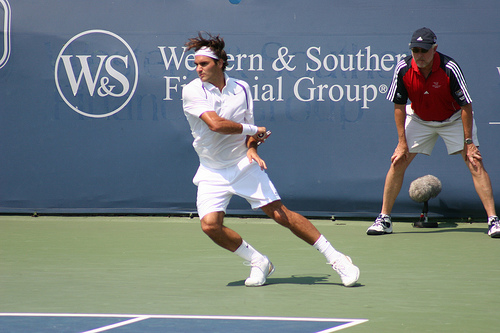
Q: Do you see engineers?
A: No, there are no engineers.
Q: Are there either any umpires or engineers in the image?
A: No, there are no engineers or umpires.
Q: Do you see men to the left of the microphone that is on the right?
A: Yes, there is a man to the left of the microphone.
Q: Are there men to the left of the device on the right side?
A: Yes, there is a man to the left of the microphone.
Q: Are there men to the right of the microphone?
A: No, the man is to the left of the microphone.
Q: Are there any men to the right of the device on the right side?
A: No, the man is to the left of the microphone.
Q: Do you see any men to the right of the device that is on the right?
A: No, the man is to the left of the microphone.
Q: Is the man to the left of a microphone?
A: Yes, the man is to the left of a microphone.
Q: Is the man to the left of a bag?
A: No, the man is to the left of a microphone.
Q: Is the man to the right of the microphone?
A: No, the man is to the left of the microphone.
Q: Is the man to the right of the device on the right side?
A: No, the man is to the left of the microphone.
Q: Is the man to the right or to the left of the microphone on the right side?
A: The man is to the left of the microphone.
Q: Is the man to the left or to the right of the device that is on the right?
A: The man is to the left of the microphone.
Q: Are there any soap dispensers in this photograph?
A: No, there are no soap dispensers.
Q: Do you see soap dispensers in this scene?
A: No, there are no soap dispensers.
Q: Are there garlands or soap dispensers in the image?
A: No, there are no soap dispensers or garlands.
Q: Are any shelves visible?
A: No, there are no shelves.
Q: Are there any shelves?
A: No, there are no shelves.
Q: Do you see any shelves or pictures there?
A: No, there are no shelves or pictures.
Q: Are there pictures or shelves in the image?
A: No, there are no shelves or pictures.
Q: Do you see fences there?
A: No, there are no fences.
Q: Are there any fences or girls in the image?
A: No, there are no fences or girls.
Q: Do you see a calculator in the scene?
A: No, there are no calculators.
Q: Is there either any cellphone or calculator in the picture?
A: No, there are no calculators or cell phones.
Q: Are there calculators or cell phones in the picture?
A: No, there are no calculators or cell phones.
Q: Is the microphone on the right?
A: Yes, the microphone is on the right of the image.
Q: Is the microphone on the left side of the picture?
A: No, the microphone is on the right of the image.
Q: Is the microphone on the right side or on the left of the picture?
A: The microphone is on the right of the image.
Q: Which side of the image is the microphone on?
A: The microphone is on the right of the image.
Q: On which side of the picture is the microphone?
A: The microphone is on the right of the image.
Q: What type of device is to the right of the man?
A: The device is a microphone.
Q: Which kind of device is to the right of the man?
A: The device is a microphone.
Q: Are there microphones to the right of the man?
A: Yes, there is a microphone to the right of the man.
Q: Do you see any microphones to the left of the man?
A: No, the microphone is to the right of the man.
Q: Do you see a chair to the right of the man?
A: No, there is a microphone to the right of the man.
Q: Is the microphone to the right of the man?
A: Yes, the microphone is to the right of the man.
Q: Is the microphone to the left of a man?
A: No, the microphone is to the right of a man.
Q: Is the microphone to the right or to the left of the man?
A: The microphone is to the right of the man.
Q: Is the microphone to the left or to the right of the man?
A: The microphone is to the right of the man.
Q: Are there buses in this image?
A: No, there are no buses.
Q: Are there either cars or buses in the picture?
A: No, there are no buses or cars.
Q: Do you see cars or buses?
A: No, there are no buses or cars.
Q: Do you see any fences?
A: No, there are no fences.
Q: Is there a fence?
A: No, there are no fences.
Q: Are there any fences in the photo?
A: No, there are no fences.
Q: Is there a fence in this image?
A: No, there are no fences.